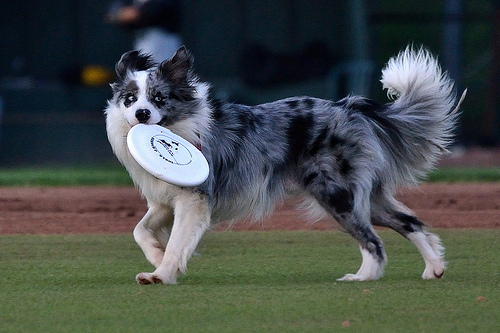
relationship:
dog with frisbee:
[88, 45, 491, 288] [125, 127, 221, 189]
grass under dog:
[425, 303, 474, 325] [88, 45, 491, 288]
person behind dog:
[112, 11, 209, 47] [88, 45, 491, 288]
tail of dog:
[366, 60, 462, 193] [88, 45, 491, 288]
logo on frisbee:
[149, 136, 196, 171] [125, 127, 221, 189]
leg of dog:
[135, 205, 168, 270] [88, 45, 491, 288]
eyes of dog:
[109, 90, 176, 102] [88, 45, 491, 288]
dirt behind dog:
[52, 194, 93, 225] [88, 45, 491, 288]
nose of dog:
[132, 107, 150, 124] [88, 45, 491, 288]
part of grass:
[68, 170, 106, 186] [425, 303, 474, 325]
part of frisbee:
[126, 125, 154, 150] [125, 127, 221, 189]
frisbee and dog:
[125, 127, 221, 189] [88, 45, 491, 288]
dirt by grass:
[52, 194, 93, 225] [425, 303, 474, 325]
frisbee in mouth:
[125, 127, 221, 189] [117, 112, 139, 126]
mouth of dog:
[117, 112, 139, 126] [88, 45, 491, 288]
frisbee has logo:
[125, 127, 221, 189] [149, 136, 196, 171]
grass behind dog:
[425, 303, 474, 325] [88, 45, 491, 288]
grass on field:
[425, 303, 474, 325] [43, 236, 107, 313]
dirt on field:
[52, 194, 93, 225] [43, 236, 107, 313]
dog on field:
[88, 45, 491, 288] [43, 236, 107, 313]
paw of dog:
[413, 226, 439, 272] [88, 45, 491, 288]